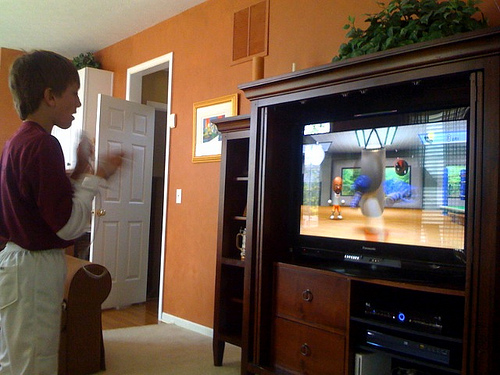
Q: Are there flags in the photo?
A: No, there are no flags.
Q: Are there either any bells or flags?
A: No, there are no flags or bells.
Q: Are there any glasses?
A: No, there are no glasses.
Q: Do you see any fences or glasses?
A: No, there are no glasses or fences.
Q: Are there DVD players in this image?
A: Yes, there is a DVD player.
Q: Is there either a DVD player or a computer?
A: Yes, there is a DVD player.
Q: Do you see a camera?
A: No, there are no cameras.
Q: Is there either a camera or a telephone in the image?
A: No, there are no cameras or phones.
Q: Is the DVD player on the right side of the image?
A: Yes, the DVD player is on the right of the image.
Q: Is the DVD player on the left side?
A: No, the DVD player is on the right of the image.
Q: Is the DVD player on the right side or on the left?
A: The DVD player is on the right of the image.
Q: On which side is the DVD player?
A: The DVD player is on the right of the image.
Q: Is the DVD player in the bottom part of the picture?
A: Yes, the DVD player is in the bottom of the image.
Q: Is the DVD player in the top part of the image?
A: No, the DVD player is in the bottom of the image.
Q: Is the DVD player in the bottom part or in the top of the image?
A: The DVD player is in the bottom of the image.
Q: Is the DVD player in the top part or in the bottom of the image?
A: The DVD player is in the bottom of the image.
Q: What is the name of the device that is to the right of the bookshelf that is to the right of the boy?
A: The device is a DVD player.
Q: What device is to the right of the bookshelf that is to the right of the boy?
A: The device is a DVD player.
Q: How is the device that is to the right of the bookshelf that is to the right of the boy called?
A: The device is a DVD player.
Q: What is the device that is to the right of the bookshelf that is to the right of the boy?
A: The device is a DVD player.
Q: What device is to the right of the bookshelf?
A: The device is a DVD player.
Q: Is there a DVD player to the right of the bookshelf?
A: Yes, there is a DVD player to the right of the bookshelf.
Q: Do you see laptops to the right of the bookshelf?
A: No, there is a DVD player to the right of the bookshelf.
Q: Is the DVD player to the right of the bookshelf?
A: Yes, the DVD player is to the right of the bookshelf.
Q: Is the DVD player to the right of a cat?
A: No, the DVD player is to the right of the bookshelf.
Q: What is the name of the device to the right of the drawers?
A: The device is a DVD player.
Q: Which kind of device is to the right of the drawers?
A: The device is a DVD player.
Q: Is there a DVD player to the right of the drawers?
A: Yes, there is a DVD player to the right of the drawers.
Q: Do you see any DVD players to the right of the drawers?
A: Yes, there is a DVD player to the right of the drawers.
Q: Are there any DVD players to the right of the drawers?
A: Yes, there is a DVD player to the right of the drawers.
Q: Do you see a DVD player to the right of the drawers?
A: Yes, there is a DVD player to the right of the drawers.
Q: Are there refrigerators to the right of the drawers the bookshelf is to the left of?
A: No, there is a DVD player to the right of the drawers.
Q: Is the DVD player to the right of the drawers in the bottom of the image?
A: Yes, the DVD player is to the right of the drawers.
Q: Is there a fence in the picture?
A: No, there are no fences.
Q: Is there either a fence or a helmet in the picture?
A: No, there are no fences or helmets.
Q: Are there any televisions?
A: Yes, there is a television.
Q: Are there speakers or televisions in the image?
A: Yes, there is a television.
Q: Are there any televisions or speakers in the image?
A: Yes, there is a television.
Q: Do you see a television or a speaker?
A: Yes, there is a television.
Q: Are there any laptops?
A: No, there are no laptops.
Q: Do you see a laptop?
A: No, there are no laptops.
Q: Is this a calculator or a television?
A: This is a television.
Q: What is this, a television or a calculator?
A: This is a television.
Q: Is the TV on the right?
A: Yes, the TV is on the right of the image.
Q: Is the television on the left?
A: No, the television is on the right of the image.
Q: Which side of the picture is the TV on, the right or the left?
A: The TV is on the right of the image.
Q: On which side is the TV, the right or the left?
A: The TV is on the right of the image.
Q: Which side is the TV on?
A: The TV is on the right of the image.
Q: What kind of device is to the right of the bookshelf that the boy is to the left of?
A: The device is a television.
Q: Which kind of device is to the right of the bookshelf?
A: The device is a television.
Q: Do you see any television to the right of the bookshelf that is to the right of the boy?
A: Yes, there is a television to the right of the bookshelf.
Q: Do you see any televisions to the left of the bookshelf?
A: No, the television is to the right of the bookshelf.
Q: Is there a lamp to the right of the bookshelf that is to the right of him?
A: No, there is a television to the right of the bookshelf.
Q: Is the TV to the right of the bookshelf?
A: Yes, the TV is to the right of the bookshelf.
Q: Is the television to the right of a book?
A: No, the television is to the right of the bookshelf.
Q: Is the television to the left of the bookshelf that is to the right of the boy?
A: No, the television is to the right of the bookshelf.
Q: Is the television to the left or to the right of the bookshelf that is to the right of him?
A: The television is to the right of the bookshelf.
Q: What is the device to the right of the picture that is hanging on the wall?
A: The device is a television.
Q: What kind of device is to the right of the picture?
A: The device is a television.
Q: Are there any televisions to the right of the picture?
A: Yes, there is a television to the right of the picture.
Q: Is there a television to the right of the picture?
A: Yes, there is a television to the right of the picture.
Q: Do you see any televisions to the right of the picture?
A: Yes, there is a television to the right of the picture.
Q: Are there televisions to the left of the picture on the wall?
A: No, the television is to the right of the picture.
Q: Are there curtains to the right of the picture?
A: No, there is a television to the right of the picture.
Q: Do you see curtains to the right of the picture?
A: No, there is a television to the right of the picture.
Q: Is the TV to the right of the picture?
A: Yes, the TV is to the right of the picture.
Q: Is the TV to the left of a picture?
A: No, the TV is to the right of a picture.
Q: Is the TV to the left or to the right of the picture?
A: The TV is to the right of the picture.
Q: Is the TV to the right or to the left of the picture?
A: The TV is to the right of the picture.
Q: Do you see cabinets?
A: Yes, there is a cabinet.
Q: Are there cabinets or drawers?
A: Yes, there is a cabinet.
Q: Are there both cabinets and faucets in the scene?
A: No, there is a cabinet but no faucets.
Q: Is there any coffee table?
A: No, there are no coffee tables.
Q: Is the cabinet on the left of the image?
A: Yes, the cabinet is on the left of the image.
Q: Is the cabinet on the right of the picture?
A: No, the cabinet is on the left of the image.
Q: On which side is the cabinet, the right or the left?
A: The cabinet is on the left of the image.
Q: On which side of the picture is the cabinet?
A: The cabinet is on the left of the image.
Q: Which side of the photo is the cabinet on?
A: The cabinet is on the left of the image.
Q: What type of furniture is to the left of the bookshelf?
A: The piece of furniture is a cabinet.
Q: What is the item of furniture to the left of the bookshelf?
A: The piece of furniture is a cabinet.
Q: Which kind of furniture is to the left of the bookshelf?
A: The piece of furniture is a cabinet.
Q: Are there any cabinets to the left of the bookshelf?
A: Yes, there is a cabinet to the left of the bookshelf.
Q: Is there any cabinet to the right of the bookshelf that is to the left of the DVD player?
A: No, the cabinet is to the left of the bookshelf.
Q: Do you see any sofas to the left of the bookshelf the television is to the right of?
A: No, there is a cabinet to the left of the bookshelf.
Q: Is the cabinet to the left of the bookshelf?
A: Yes, the cabinet is to the left of the bookshelf.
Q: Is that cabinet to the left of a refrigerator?
A: No, the cabinet is to the left of the bookshelf.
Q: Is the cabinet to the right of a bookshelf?
A: No, the cabinet is to the left of a bookshelf.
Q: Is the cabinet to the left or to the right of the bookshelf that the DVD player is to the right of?
A: The cabinet is to the left of the bookshelf.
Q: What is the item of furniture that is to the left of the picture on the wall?
A: The piece of furniture is a cabinet.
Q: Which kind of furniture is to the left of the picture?
A: The piece of furniture is a cabinet.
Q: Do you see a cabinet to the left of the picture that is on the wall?
A: Yes, there is a cabinet to the left of the picture.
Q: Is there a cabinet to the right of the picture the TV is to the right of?
A: No, the cabinet is to the left of the picture.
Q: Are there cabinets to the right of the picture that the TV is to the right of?
A: No, the cabinet is to the left of the picture.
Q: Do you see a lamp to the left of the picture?
A: No, there is a cabinet to the left of the picture.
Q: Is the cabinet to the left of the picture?
A: Yes, the cabinet is to the left of the picture.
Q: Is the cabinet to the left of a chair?
A: No, the cabinet is to the left of the picture.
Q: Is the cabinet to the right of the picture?
A: No, the cabinet is to the left of the picture.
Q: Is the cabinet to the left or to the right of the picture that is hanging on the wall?
A: The cabinet is to the left of the picture.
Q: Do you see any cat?
A: No, there are no cats.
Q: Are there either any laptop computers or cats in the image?
A: No, there are no cats or laptop computers.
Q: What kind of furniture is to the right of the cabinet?
A: The piece of furniture is a bookshelf.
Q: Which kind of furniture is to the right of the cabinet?
A: The piece of furniture is a bookshelf.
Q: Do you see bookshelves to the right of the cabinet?
A: Yes, there is a bookshelf to the right of the cabinet.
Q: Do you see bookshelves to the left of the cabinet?
A: No, the bookshelf is to the right of the cabinet.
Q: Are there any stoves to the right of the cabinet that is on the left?
A: No, there is a bookshelf to the right of the cabinet.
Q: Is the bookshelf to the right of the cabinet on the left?
A: Yes, the bookshelf is to the right of the cabinet.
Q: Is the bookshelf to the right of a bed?
A: No, the bookshelf is to the right of the cabinet.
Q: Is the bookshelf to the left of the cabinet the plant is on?
A: No, the bookshelf is to the right of the cabinet.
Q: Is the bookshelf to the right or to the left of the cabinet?
A: The bookshelf is to the right of the cabinet.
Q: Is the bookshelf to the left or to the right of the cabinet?
A: The bookshelf is to the right of the cabinet.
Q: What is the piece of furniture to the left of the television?
A: The piece of furniture is a bookshelf.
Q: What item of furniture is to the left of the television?
A: The piece of furniture is a bookshelf.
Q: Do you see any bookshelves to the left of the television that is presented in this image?
A: Yes, there is a bookshelf to the left of the television.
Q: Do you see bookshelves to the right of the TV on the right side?
A: No, the bookshelf is to the left of the TV.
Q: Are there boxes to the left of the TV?
A: No, there is a bookshelf to the left of the TV.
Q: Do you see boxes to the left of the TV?
A: No, there is a bookshelf to the left of the TV.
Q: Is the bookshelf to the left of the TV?
A: Yes, the bookshelf is to the left of the TV.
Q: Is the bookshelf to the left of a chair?
A: No, the bookshelf is to the left of the TV.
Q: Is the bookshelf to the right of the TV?
A: No, the bookshelf is to the left of the TV.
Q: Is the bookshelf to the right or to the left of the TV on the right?
A: The bookshelf is to the left of the television.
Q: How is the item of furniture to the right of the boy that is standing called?
A: The piece of furniture is a bookshelf.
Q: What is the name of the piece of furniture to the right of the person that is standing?
A: The piece of furniture is a bookshelf.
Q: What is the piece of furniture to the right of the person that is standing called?
A: The piece of furniture is a bookshelf.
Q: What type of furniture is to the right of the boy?
A: The piece of furniture is a bookshelf.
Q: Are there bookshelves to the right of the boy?
A: Yes, there is a bookshelf to the right of the boy.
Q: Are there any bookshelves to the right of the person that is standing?
A: Yes, there is a bookshelf to the right of the boy.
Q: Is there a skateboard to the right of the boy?
A: No, there is a bookshelf to the right of the boy.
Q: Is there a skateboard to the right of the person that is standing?
A: No, there is a bookshelf to the right of the boy.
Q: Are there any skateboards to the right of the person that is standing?
A: No, there is a bookshelf to the right of the boy.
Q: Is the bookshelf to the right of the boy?
A: Yes, the bookshelf is to the right of the boy.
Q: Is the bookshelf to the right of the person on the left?
A: Yes, the bookshelf is to the right of the boy.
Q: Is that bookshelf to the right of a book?
A: No, the bookshelf is to the right of the boy.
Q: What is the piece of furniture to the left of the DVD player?
A: The piece of furniture is a bookshelf.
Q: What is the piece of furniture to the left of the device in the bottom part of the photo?
A: The piece of furniture is a bookshelf.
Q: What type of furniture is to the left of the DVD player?
A: The piece of furniture is a bookshelf.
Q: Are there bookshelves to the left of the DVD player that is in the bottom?
A: Yes, there is a bookshelf to the left of the DVD player.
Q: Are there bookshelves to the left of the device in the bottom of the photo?
A: Yes, there is a bookshelf to the left of the DVD player.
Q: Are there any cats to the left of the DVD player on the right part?
A: No, there is a bookshelf to the left of the DVD player.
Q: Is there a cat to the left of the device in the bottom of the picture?
A: No, there is a bookshelf to the left of the DVD player.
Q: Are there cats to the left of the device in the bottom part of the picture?
A: No, there is a bookshelf to the left of the DVD player.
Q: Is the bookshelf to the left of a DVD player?
A: Yes, the bookshelf is to the left of a DVD player.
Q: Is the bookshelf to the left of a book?
A: No, the bookshelf is to the left of a DVD player.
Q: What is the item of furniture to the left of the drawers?
A: The piece of furniture is a bookshelf.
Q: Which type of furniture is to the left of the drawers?
A: The piece of furniture is a bookshelf.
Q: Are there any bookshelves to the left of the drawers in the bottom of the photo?
A: Yes, there is a bookshelf to the left of the drawers.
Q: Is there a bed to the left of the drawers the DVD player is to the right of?
A: No, there is a bookshelf to the left of the drawers.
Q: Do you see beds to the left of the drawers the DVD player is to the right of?
A: No, there is a bookshelf to the left of the drawers.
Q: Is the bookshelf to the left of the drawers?
A: Yes, the bookshelf is to the left of the drawers.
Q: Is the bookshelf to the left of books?
A: No, the bookshelf is to the left of the drawers.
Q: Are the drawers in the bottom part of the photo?
A: Yes, the drawers are in the bottom of the image.